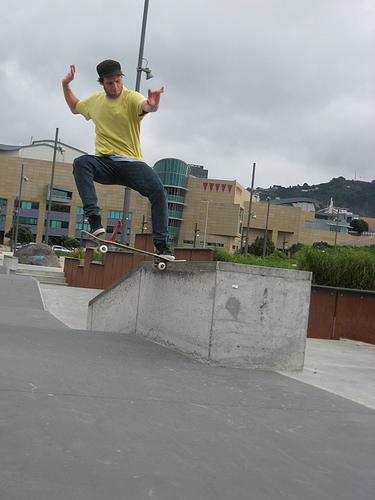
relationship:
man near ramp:
[60, 58, 177, 265] [84, 254, 308, 373]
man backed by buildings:
[60, 58, 177, 265] [4, 140, 359, 254]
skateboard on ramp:
[79, 226, 187, 272] [84, 254, 308, 373]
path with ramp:
[0, 273, 374, 499] [84, 254, 308, 373]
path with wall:
[0, 273, 374, 499] [61, 232, 373, 345]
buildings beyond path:
[3, 124, 362, 265] [0, 273, 374, 499]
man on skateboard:
[60, 60, 182, 260] [79, 226, 187, 272]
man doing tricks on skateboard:
[60, 60, 182, 260] [79, 226, 187, 272]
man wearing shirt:
[60, 60, 182, 260] [74, 89, 149, 158]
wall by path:
[85, 261, 314, 373] [4, 272, 349, 484]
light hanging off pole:
[138, 64, 154, 81] [117, 7, 150, 240]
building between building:
[151, 155, 189, 258] [178, 173, 336, 245]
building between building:
[151, 155, 189, 258] [5, 152, 150, 250]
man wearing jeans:
[60, 58, 177, 265] [69, 151, 173, 241]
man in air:
[60, 60, 182, 260] [80, 267, 190, 367]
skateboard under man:
[79, 226, 187, 272] [60, 60, 182, 260]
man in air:
[60, 60, 182, 260] [81, 270, 201, 356]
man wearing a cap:
[60, 60, 182, 260] [96, 57, 124, 77]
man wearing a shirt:
[60, 60, 182, 260] [74, 82, 151, 164]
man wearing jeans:
[60, 60, 182, 260] [69, 151, 173, 241]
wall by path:
[85, 261, 314, 373] [0, 273, 374, 499]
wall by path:
[61, 232, 373, 345] [0, 273, 374, 499]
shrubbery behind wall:
[216, 242, 363, 284] [61, 232, 373, 345]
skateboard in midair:
[79, 226, 187, 272] [80, 270, 195, 356]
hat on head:
[95, 59, 124, 80] [94, 57, 123, 95]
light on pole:
[20, 173, 29, 183] [10, 162, 24, 250]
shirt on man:
[74, 89, 149, 158] [60, 60, 182, 260]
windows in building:
[13, 199, 40, 211] [2, 148, 147, 245]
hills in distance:
[246, 176, 374, 218] [263, 173, 360, 207]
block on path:
[84, 255, 314, 370] [0, 273, 374, 499]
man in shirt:
[60, 60, 182, 260] [74, 89, 149, 158]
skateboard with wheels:
[79, 226, 187, 272] [91, 242, 107, 255]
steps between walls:
[19, 265, 68, 285] [1, 250, 86, 289]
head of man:
[98, 59, 125, 99] [60, 58, 177, 265]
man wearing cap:
[60, 58, 177, 265] [96, 57, 124, 77]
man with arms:
[60, 60, 182, 260] [60, 64, 162, 121]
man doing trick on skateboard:
[60, 58, 177, 265] [79, 226, 187, 272]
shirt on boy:
[74, 82, 151, 164] [61, 59, 181, 252]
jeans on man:
[71, 152, 161, 237] [60, 58, 177, 265]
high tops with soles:
[88, 215, 176, 260] [90, 224, 173, 260]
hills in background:
[244, 173, 372, 215] [2, 17, 370, 213]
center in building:
[149, 154, 193, 244] [2, 155, 368, 243]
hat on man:
[92, 56, 126, 83] [60, 58, 177, 265]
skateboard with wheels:
[77, 227, 188, 265] [90, 242, 173, 271]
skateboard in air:
[77, 227, 188, 265] [4, 18, 195, 322]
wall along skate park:
[61, 242, 372, 345] [2, 266, 372, 497]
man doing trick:
[60, 58, 177, 265] [40, 56, 192, 300]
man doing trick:
[60, 58, 177, 265] [53, 53, 190, 295]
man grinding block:
[60, 58, 177, 265] [86, 257, 313, 373]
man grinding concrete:
[60, 58, 177, 265] [86, 258, 318, 377]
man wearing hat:
[60, 58, 177, 265] [94, 57, 127, 81]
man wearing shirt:
[60, 58, 177, 265] [74, 82, 151, 164]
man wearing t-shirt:
[60, 58, 177, 265] [73, 84, 143, 165]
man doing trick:
[60, 58, 177, 265] [53, 53, 307, 367]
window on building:
[18, 201, 26, 209] [2, 152, 363, 260]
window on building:
[25, 198, 31, 207] [2, 152, 363, 260]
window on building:
[104, 207, 111, 217] [2, 152, 363, 260]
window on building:
[110, 209, 116, 216] [2, 152, 363, 260]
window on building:
[54, 220, 61, 228] [2, 152, 363, 260]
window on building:
[28, 216, 36, 225] [2, 152, 363, 260]